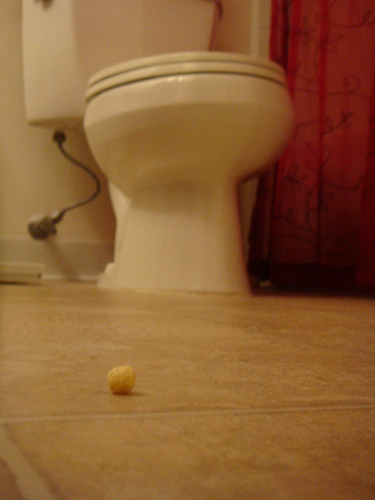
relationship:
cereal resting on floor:
[108, 364, 135, 392] [4, 296, 366, 492]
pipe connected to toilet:
[24, 123, 107, 245] [21, 0, 296, 294]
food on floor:
[105, 365, 136, 394] [4, 296, 366, 492]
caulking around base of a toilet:
[104, 273, 286, 327] [108, 14, 260, 152]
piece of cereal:
[110, 370, 126, 390] [106, 363, 136, 393]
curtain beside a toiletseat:
[247, 6, 374, 292] [84, 48, 295, 297]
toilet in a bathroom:
[21, 0, 296, 294] [1, 1, 373, 498]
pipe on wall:
[27, 130, 103, 240] [0, 0, 256, 287]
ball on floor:
[109, 351, 134, 402] [2, 283, 374, 498]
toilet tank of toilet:
[19, 0, 226, 128] [3, 0, 215, 119]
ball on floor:
[107, 363, 135, 394] [151, 314, 350, 413]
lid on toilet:
[90, 55, 286, 76] [90, 19, 282, 277]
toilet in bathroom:
[71, 45, 302, 303] [1, 1, 373, 498]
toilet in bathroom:
[21, 0, 296, 294] [1, 1, 373, 498]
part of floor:
[188, 332, 271, 384] [2, 283, 374, 498]